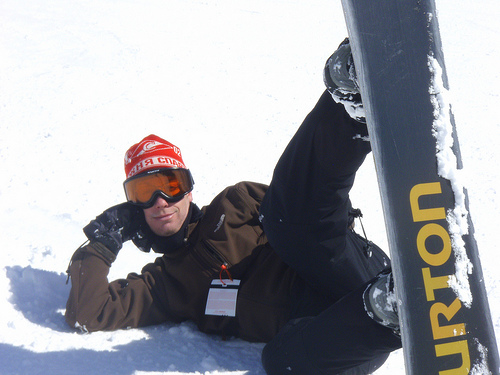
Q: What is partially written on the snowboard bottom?
A: URTON.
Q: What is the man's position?
A: He is lying down.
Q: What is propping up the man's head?
A: His hand.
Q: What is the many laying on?
A: Snow.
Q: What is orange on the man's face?
A: Goggles.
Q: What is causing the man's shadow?
A: Sunlight.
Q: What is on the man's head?
A: Ski cap.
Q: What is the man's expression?
A: He is smiling.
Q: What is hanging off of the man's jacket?
A: A tag.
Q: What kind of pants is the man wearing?
A: Black snow-pants.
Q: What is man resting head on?
A: Elbow.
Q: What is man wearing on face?
A: Goggles.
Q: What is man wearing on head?
A: Hat.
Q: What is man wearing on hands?
A: Gloves.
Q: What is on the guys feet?
A: A snowboard.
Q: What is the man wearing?
A: A fuzzy jacket.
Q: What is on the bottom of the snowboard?
A: Yellow writing.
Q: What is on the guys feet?
A: A long black snowboard.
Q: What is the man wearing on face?
A: Goggles.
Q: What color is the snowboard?
A: Black.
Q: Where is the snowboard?
A: At his feet.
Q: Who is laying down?
A: The man.